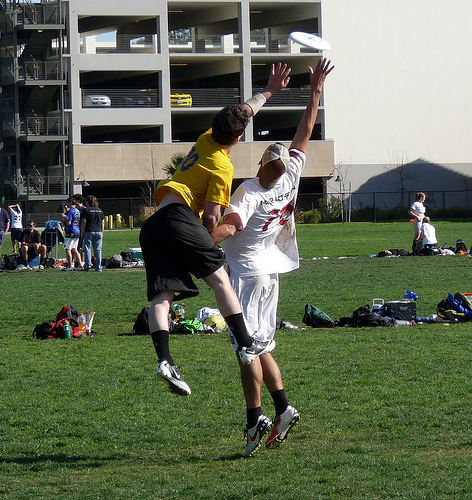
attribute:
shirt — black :
[23, 229, 41, 244]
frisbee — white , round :
[286, 27, 331, 55]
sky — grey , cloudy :
[343, 11, 465, 145]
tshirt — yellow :
[135, 103, 265, 211]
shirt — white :
[411, 200, 429, 219]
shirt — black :
[80, 203, 105, 229]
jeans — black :
[84, 228, 103, 268]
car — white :
[76, 77, 158, 132]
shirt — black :
[151, 139, 231, 197]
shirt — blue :
[236, 172, 312, 253]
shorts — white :
[228, 255, 306, 358]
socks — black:
[241, 398, 266, 420]